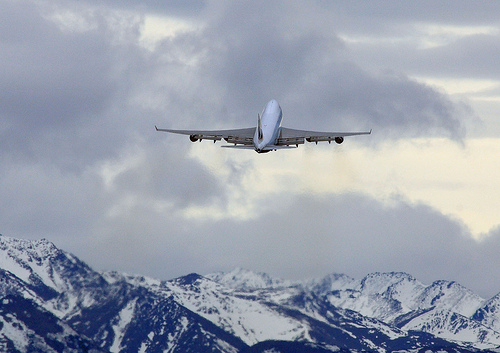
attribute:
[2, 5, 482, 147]
clouds — white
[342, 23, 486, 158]
white clouds — blue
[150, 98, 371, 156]
plane — gray, cloudy 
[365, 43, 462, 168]
clouds — white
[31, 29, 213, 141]
sky — blue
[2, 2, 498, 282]
clouds — white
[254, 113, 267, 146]
tail — apart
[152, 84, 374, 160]
plane — white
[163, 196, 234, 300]
clouds — white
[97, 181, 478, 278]
clouds — white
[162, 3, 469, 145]
cloud —  blue 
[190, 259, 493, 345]
mountain — Large 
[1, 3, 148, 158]
clouds — white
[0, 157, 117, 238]
clouds — white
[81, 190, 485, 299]
clouds — white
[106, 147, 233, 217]
clouds — white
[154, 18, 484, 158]
clouds — white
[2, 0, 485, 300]
sky — cloudy 